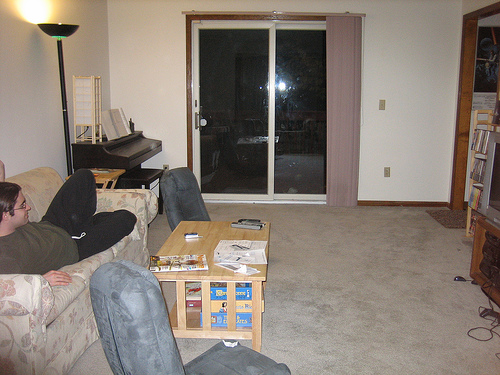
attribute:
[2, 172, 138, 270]
man — young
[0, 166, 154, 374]
couch — floral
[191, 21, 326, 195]
door — glass, closed, glas, large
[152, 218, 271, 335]
coffee table — present, cluttered, wooden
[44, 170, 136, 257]
pants — black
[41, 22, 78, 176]
lamp — on, black, emitting light, tall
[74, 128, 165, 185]
piano — black, in the corner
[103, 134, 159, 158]
lid — closed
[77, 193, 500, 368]
carpet — dirty, beige, brown, grey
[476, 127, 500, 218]
tv — off, silver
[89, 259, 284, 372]
chair — small, blue, grey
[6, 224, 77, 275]
shirt — green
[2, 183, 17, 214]
hair — brown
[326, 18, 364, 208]
curtain — pulled to the side